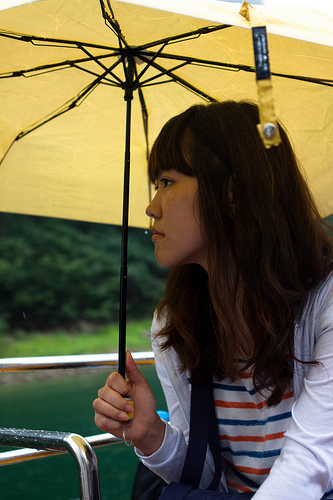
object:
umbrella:
[0, 0, 333, 232]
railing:
[0, 346, 155, 500]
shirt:
[133, 270, 332, 500]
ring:
[122, 424, 133, 447]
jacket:
[134, 271, 333, 500]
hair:
[147, 100, 333, 409]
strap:
[179, 374, 210, 493]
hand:
[92, 349, 157, 442]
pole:
[118, 98, 132, 378]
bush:
[0, 214, 168, 338]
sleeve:
[247, 313, 332, 500]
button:
[262, 121, 277, 140]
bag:
[157, 480, 253, 496]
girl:
[91, 99, 333, 491]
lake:
[0, 366, 170, 500]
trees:
[0, 212, 64, 336]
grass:
[0, 319, 151, 358]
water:
[0, 359, 168, 497]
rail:
[0, 426, 102, 500]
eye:
[160, 176, 177, 190]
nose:
[145, 187, 162, 219]